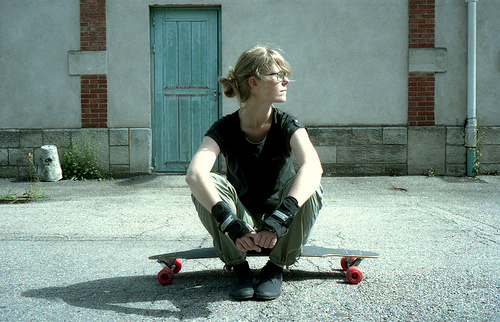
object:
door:
[148, 4, 222, 175]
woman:
[184, 42, 324, 302]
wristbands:
[257, 195, 301, 239]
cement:
[0, 183, 180, 322]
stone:
[37, 144, 64, 183]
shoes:
[254, 263, 284, 300]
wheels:
[345, 265, 363, 284]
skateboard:
[147, 244, 381, 286]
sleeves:
[203, 114, 233, 154]